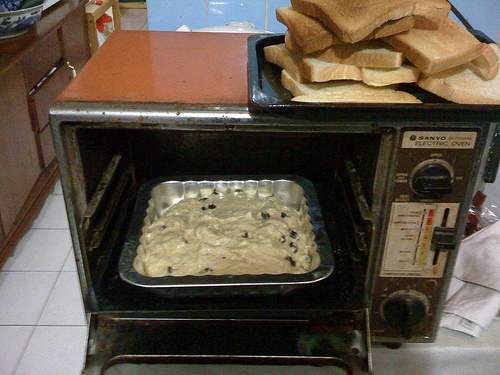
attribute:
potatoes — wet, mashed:
[150, 186, 308, 283]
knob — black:
[415, 156, 458, 203]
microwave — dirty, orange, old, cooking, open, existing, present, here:
[53, 28, 480, 291]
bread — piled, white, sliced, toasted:
[255, 1, 497, 105]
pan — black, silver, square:
[241, 31, 499, 110]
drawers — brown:
[6, 24, 89, 156]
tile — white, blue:
[9, 172, 93, 372]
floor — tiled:
[14, 182, 145, 372]